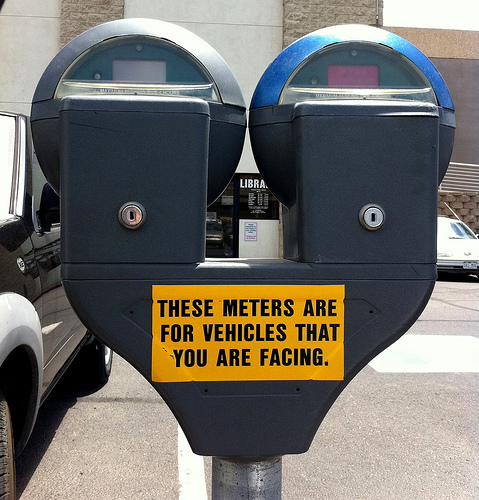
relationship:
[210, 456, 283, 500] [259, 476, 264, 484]
post has spot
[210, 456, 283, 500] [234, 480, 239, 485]
post has spot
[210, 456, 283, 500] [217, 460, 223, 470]
post has spot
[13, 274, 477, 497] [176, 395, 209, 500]
sidewalk has line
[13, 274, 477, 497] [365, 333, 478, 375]
sidewalk has line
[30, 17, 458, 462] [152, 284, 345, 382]
parking meter has sign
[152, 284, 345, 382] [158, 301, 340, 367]
sign has wording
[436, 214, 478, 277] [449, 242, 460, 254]
car has section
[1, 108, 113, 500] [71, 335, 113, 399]
car has wheel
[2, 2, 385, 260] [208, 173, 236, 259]
building has window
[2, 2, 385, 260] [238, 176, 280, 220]
building has window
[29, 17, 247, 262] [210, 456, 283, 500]
meter mounted on post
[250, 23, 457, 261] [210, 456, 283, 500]
meter mounted on post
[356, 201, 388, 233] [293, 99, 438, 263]
bolt on back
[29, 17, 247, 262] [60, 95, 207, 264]
meter has back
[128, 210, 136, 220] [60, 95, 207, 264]
keyhole on back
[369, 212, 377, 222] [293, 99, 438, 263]
keyhole on back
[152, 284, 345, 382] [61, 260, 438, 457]
sign on back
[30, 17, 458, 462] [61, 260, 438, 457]
parking meter has back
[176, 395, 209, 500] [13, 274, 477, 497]
line painted on sidewalk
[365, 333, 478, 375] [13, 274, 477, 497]
line painted on sidewalk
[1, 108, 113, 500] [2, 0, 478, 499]
car in parking lot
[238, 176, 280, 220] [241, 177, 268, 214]
window has lettering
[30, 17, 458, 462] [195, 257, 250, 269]
parking meter has a spot of sunlight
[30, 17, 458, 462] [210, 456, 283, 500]
parking meter attached to post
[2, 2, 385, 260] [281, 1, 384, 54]
building has wall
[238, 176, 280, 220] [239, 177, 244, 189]
window has letter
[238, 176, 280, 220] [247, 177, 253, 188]
window has letter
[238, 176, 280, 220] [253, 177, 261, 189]
window has letter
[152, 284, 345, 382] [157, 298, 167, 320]
sign has letter t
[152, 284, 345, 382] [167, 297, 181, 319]
sign has letter h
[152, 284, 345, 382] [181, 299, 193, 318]
sign has letter e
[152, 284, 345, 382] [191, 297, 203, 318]
sign has letter s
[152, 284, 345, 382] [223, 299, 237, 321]
sign has letter m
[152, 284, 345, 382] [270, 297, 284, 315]
sign has letter r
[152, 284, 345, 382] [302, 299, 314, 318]
sign has letter a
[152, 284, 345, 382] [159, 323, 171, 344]
sign has letter f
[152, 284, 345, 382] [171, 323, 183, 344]
sign has letter o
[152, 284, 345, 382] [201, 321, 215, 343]
sign has letter v